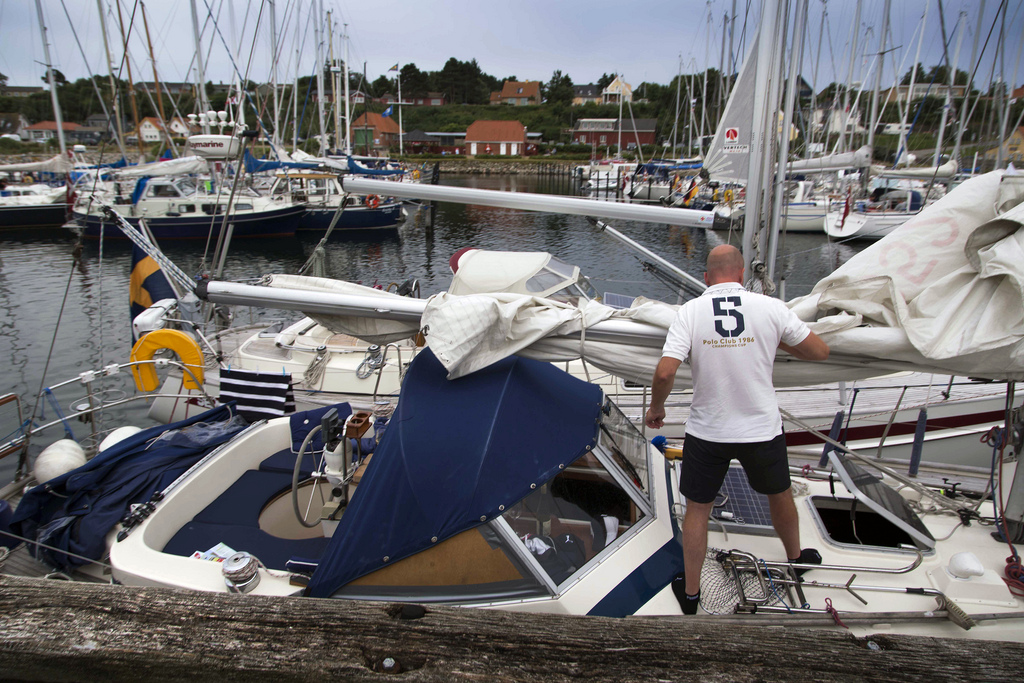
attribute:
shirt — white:
[654, 297, 842, 450]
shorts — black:
[644, 402, 847, 542]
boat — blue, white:
[110, 143, 303, 286]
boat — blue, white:
[145, 336, 553, 590]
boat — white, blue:
[289, 173, 413, 241]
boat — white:
[800, 170, 931, 254]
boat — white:
[766, 167, 852, 232]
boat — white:
[618, 160, 698, 199]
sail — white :
[773, 157, 1023, 379]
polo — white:
[661, 287, 808, 437]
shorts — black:
[684, 427, 789, 498]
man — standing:
[655, 242, 830, 619]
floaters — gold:
[125, 328, 202, 399]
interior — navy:
[26, 392, 362, 585]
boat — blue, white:
[61, 157, 303, 250]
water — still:
[4, 160, 897, 475]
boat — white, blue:
[264, 163, 407, 239]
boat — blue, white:
[5, 168, 75, 229]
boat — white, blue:
[819, 161, 955, 235]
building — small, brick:
[459, 114, 539, 159]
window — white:
[466, 133, 480, 159]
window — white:
[494, 138, 511, 167]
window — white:
[507, 132, 528, 158]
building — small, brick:
[352, 110, 411, 156]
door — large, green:
[352, 127, 375, 156]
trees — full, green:
[440, 59, 483, 105]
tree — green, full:
[399, 57, 431, 99]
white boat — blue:
[38, 356, 1021, 658]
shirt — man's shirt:
[639, 285, 813, 453]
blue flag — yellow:
[111, 239, 184, 351]